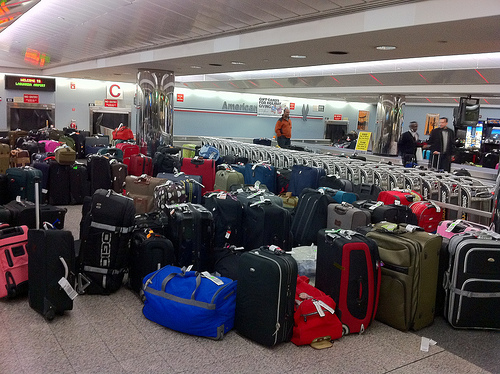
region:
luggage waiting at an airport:
[0, 129, 497, 350]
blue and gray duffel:
[139, 262, 236, 341]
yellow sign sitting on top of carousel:
[355, 131, 370, 152]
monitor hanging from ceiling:
[451, 95, 481, 127]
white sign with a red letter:
[106, 82, 125, 99]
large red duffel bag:
[293, 273, 344, 347]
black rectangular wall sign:
[3, 73, 56, 92]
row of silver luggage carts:
[199, 134, 490, 226]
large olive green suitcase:
[366, 220, 441, 329]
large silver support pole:
[137, 71, 174, 158]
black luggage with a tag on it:
[26, 224, 79, 325]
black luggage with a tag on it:
[86, 187, 136, 291]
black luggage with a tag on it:
[241, 247, 296, 357]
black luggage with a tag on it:
[164, 193, 206, 261]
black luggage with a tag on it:
[217, 182, 244, 239]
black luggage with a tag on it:
[248, 182, 283, 232]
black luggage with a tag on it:
[93, 150, 115, 185]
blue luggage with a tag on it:
[141, 261, 230, 341]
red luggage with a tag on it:
[287, 272, 332, 346]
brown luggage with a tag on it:
[383, 224, 436, 338]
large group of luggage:
[3, 125, 499, 347]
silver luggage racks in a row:
[198, 135, 490, 222]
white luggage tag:
[198, 268, 224, 285]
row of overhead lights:
[78, 44, 409, 79]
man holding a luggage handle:
[424, 116, 456, 169]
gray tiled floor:
[3, 285, 486, 371]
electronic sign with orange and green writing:
[4, 73, 55, 91]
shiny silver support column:
[135, 68, 175, 147]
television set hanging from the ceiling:
[452, 93, 481, 128]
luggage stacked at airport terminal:
[3, 2, 496, 372]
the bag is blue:
[166, 288, 192, 316]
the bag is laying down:
[301, 290, 325, 329]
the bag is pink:
[3, 248, 28, 268]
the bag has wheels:
[42, 302, 60, 327]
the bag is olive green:
[407, 260, 429, 290]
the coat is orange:
[281, 120, 288, 132]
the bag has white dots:
[166, 186, 181, 200]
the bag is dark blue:
[293, 168, 309, 187]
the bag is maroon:
[134, 157, 145, 170]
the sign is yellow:
[358, 134, 368, 149]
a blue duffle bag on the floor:
[97, 251, 284, 366]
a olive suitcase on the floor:
[369, 207, 440, 346]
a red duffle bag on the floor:
[276, 266, 344, 353]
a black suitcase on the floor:
[235, 243, 290, 361]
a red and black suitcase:
[317, 215, 383, 331]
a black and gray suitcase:
[441, 224, 496, 349]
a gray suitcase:
[326, 176, 371, 238]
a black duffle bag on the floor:
[67, 182, 145, 331]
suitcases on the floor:
[50, 138, 487, 335]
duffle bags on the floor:
[59, 158, 355, 338]